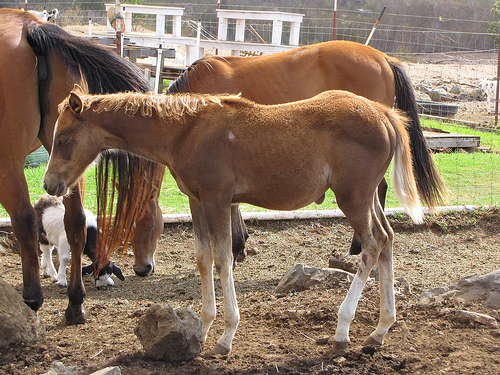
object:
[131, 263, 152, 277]
nose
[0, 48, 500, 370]
ground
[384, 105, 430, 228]
tail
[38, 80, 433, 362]
horse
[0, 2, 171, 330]
horse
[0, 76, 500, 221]
grass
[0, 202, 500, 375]
brown dirt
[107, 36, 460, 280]
horse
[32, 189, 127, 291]
goat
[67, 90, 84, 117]
ear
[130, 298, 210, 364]
rock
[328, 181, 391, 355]
legs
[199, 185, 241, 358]
legs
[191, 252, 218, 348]
bottom legs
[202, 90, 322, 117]
back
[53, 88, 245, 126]
hair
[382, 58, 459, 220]
tail